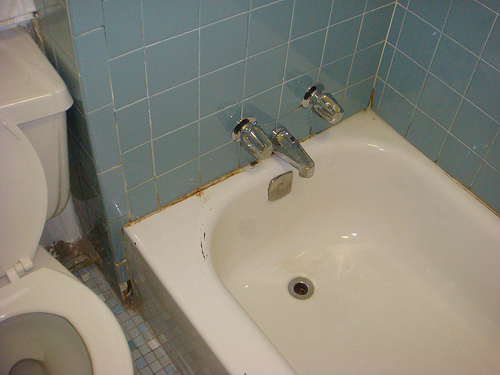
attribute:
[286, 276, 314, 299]
drain — metal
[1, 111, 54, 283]
lid — toilet, up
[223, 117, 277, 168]
knob — silver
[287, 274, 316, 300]
drain — silver 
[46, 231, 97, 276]
dirt — brown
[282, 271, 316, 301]
drain — bottom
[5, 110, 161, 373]
white plastic — white 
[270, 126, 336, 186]
spout — silver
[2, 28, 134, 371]
toilet — up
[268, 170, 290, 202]
patch — square, silver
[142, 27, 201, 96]
tile — blue 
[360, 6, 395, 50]
tile — blue 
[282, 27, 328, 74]
tile — blue 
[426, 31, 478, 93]
tile — blue , broken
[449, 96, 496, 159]
tile — blue 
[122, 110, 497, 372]
bathtub — empty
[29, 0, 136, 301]
wall — dirty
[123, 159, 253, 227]
stain — rust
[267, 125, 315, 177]
faucet — chrome 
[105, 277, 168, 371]
tile floor — blue , white 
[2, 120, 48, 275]
lid — toilet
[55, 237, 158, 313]
stains — brown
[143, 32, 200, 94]
tile — blue, broken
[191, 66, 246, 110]
tile — blue, broken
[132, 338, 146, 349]
tile — blue, broken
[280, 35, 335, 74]
tile — blue, broken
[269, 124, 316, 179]
faucet — silver 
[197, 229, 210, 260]
dirt — black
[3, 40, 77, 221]
toilet tank — white 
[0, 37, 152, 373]
toilet — white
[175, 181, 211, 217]
grout — dirty, brown